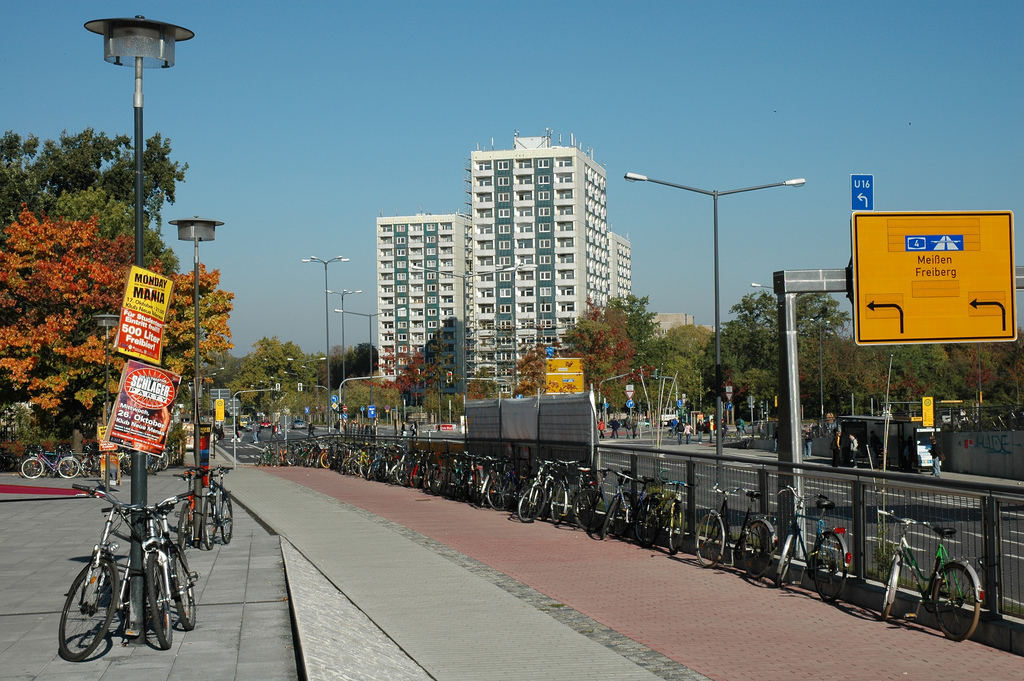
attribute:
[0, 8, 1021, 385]
sky — blue, clear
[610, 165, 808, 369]
light — tall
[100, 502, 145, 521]
seat — black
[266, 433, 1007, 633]
fence — metal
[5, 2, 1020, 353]
sky — blue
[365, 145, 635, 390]
buildings — identical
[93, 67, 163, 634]
pole — metal